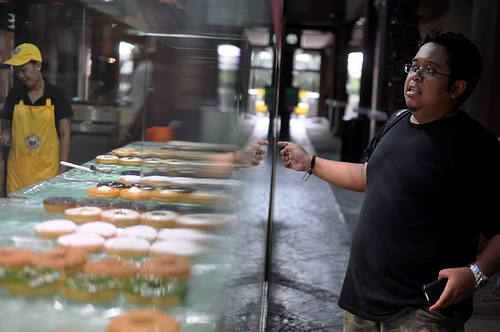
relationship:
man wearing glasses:
[275, 31, 500, 332] [403, 64, 452, 79]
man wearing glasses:
[275, 31, 500, 332] [401, 58, 438, 81]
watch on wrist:
[467, 263, 490, 293] [460, 253, 488, 291]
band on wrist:
[308, 148, 318, 176] [290, 133, 332, 189]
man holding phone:
[271, 31, 475, 330] [409, 273, 453, 307]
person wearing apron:
[10, 43, 70, 195] [10, 100, 60, 181]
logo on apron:
[20, 127, 40, 151] [10, 93, 64, 187]